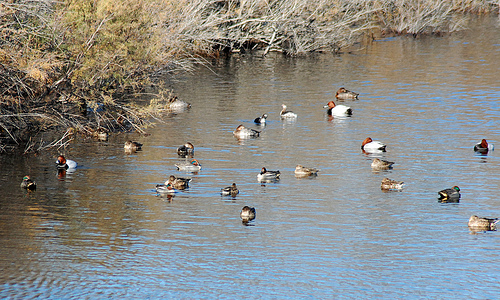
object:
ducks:
[237, 205, 258, 228]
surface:
[8, 32, 500, 300]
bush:
[0, 2, 450, 105]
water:
[3, 233, 472, 299]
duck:
[322, 100, 356, 121]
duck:
[252, 163, 284, 184]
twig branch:
[14, 6, 312, 52]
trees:
[90, 0, 117, 43]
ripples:
[381, 244, 425, 247]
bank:
[5, 5, 498, 74]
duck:
[379, 174, 408, 194]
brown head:
[380, 172, 392, 184]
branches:
[362, 24, 380, 31]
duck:
[160, 95, 193, 116]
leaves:
[67, 47, 72, 52]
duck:
[434, 182, 466, 206]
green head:
[453, 185, 461, 191]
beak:
[322, 105, 328, 108]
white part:
[332, 105, 345, 117]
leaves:
[143, 34, 151, 35]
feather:
[397, 180, 406, 193]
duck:
[291, 162, 321, 181]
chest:
[294, 170, 304, 177]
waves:
[451, 113, 476, 116]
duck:
[472, 137, 496, 164]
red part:
[478, 137, 490, 148]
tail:
[315, 169, 320, 172]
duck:
[18, 172, 40, 195]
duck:
[358, 134, 390, 158]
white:
[366, 143, 379, 154]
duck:
[276, 97, 301, 125]